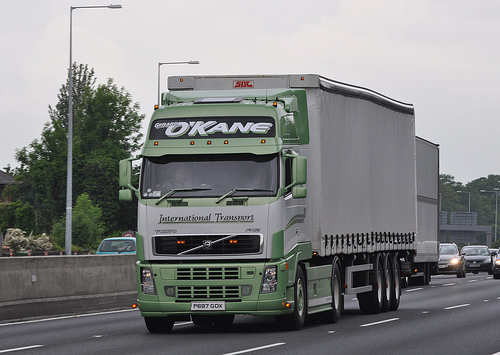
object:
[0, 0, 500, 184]
sky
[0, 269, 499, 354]
road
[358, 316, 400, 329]
line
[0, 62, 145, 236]
tree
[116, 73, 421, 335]
truck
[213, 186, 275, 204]
wiper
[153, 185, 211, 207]
wiper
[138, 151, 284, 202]
windshield